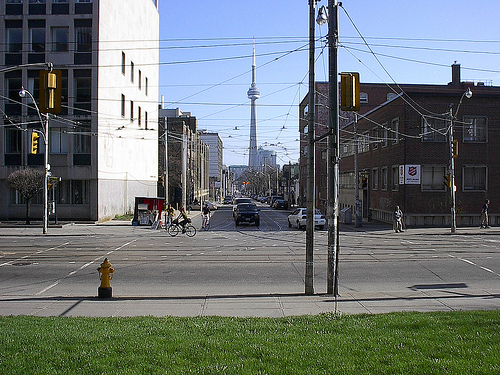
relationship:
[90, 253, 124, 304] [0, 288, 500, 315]
fire hydrant on sidewalk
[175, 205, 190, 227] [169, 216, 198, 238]
person on a bike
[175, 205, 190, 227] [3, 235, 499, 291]
person crossing street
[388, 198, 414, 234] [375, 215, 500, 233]
person on sidewalk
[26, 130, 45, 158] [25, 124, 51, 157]
cover on traffic light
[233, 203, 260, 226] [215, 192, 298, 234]
vehicle are on street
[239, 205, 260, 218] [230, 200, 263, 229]
people are in vehicle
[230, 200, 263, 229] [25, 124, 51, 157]
vehicle at traffic light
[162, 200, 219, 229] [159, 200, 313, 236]
people are on street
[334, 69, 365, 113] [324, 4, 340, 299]
street light on a utility pole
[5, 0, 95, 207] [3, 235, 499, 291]
windows are over street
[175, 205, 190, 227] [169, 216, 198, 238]
person riding a bike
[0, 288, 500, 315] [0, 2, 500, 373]
sidewalk in a city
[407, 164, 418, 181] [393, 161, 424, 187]
logo on sign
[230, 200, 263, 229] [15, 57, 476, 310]
vehicle in intersection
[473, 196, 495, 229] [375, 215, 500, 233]
man on sidewalk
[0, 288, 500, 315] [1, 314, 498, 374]
sidewalk by grass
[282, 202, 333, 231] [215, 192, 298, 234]
car on street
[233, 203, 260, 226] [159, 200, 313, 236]
vehicle are on street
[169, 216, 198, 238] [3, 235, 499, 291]
bike on street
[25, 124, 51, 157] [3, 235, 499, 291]
traffic light over street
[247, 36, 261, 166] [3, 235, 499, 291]
building are by street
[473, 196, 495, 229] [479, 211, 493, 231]
man wearing pants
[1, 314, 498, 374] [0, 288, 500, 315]
grass by sidewalk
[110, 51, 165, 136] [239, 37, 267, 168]
windows are on building